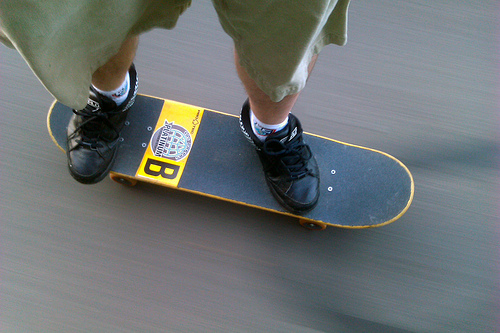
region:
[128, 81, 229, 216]
a bright yellow stripe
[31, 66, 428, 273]
a short black skateboard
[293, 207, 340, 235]
a bright orange wheel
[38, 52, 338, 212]
a pair of black tennis shoes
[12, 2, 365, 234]
a man wearing shorts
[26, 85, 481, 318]
a dark blurry ground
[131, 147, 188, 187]
a capital letter B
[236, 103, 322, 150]
a white cotton ankle sock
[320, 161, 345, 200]
a pair of screws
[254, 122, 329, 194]
a black shoe lace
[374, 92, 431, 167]
part of a road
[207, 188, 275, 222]
edge of a skateboard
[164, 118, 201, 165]
part of a skateboard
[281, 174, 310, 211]
part of a shoe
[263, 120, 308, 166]
part of shoe laces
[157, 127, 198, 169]
part of a label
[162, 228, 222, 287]
part of a road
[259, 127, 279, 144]
part of a sock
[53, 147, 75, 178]
part of a shoe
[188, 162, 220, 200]
part of a skateboard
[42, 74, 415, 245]
the skateboard is black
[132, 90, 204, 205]
the skateboard has a yellow sticker on it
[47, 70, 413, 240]
the boy is wearing black tennis shoes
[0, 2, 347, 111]
the boy is wearing khaki shorts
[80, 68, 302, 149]
the boy is wearing white socks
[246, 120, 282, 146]
the socks have a red and blue design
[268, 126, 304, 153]
the shoes have white lettering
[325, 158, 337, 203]
the skateboard has silver grommets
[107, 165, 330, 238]
the skateboard has orange wheels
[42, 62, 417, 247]
the skateboard is moving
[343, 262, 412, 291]
part of a road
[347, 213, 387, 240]
edge of a skateboard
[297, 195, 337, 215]
part of a shoe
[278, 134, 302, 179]
part of a lace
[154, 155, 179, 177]
part of a label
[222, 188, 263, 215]
edge of a skateboard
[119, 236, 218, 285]
part of a road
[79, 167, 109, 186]
edge of a shoe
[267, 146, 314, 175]
part of a shoe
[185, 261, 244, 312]
part of a road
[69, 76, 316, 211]
feet standing on the skateboard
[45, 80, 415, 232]
skateboard resting on the floor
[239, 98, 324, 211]
a black shoe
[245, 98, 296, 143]
a white sock in the black shoe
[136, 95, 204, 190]
a yellow label on the skateboard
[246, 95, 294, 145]
a white sock on a foot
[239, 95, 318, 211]
a black shoe on a foot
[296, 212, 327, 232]
a wheel under the skateboard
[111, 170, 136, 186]
a wheel on the ground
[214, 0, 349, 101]
green shorts on a leg